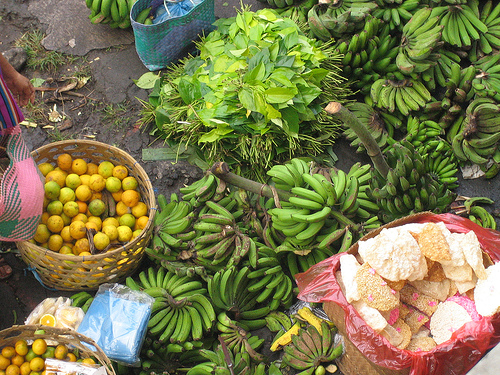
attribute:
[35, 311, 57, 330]
orange — cut 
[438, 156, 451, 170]
banana — green 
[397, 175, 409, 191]
banana — green 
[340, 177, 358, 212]
banana — green 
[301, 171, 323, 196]
banana — green 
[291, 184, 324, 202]
banana — green 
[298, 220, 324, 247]
banana — green , small 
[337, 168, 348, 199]
banana — green , small 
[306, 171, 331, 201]
banana — green , small 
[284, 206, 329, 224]
banana — green , small 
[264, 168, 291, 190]
banana — green , small 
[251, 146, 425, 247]
bananas — green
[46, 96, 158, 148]
dirt — is brown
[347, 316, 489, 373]
bag — red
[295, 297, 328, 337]
banana — ripe , yellow 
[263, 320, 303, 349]
banana — yellow , ripe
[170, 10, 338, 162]
leaves — many 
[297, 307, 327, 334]
banana — yellow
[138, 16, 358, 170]
fruit — green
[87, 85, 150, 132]
grass — little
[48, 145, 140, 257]
fruit — green and yellow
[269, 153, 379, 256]
bananas — ready 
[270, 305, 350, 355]
bananas — yellow 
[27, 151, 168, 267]
lemon — cut open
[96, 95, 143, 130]
grass — small 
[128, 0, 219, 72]
bag — blue 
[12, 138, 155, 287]
basket — brown 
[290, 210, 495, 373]
basket — large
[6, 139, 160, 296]
wicker basket — large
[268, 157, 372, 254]
bananas — different 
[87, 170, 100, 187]
fruit — round 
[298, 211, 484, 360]
lining — red 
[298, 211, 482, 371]
bag — red 